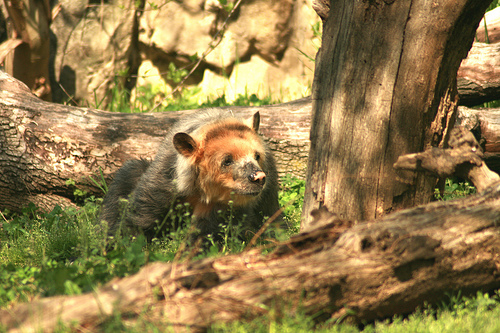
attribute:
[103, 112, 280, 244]
bear — brown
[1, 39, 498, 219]
trunk — brown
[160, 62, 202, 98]
vine leaves — brown, green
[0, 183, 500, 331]
grass — long, green, yellow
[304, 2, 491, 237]
trunk — standing, brown, tree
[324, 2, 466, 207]
tree — thick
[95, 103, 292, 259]
bear — brown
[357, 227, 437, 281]
holes — dark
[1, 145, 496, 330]
tree trunk — brown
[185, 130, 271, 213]
head — round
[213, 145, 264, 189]
face — pointed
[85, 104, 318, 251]
bear — large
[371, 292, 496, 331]
grass — green, yellow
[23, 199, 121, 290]
grass — long , green, yellow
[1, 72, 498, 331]
grass — yellow, green, long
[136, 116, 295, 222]
bear — multi colored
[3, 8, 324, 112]
wall — molded, rock style, concrete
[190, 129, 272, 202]
face — orange